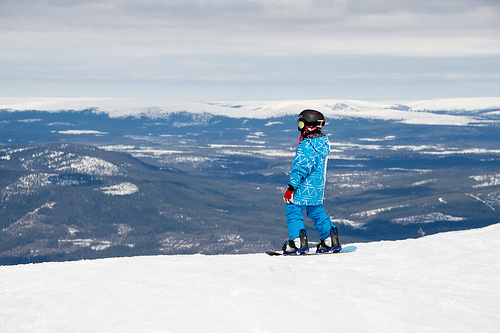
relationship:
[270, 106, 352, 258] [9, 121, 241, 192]
small snowboader contemplating view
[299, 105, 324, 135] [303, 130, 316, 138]
helmet with strap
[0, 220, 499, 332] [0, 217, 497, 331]
white snow at edge of mountain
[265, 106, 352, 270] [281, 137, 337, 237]
small snowboader dressed in blue clothes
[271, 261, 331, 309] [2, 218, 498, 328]
part of a ground